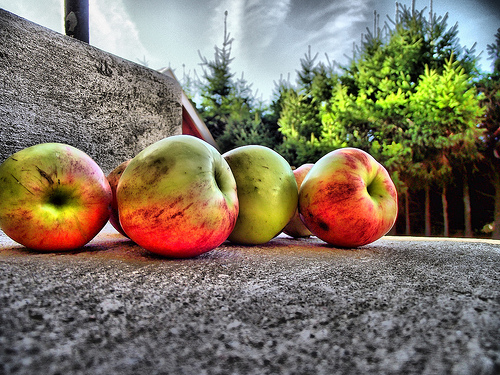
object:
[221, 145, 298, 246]
apple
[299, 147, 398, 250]
apple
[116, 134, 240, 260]
apple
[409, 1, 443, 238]
trees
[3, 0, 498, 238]
background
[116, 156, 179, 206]
marks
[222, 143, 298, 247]
skin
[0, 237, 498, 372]
ground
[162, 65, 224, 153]
roof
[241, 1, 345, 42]
clouds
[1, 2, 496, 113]
sky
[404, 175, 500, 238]
trunks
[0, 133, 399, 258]
apples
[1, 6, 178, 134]
wall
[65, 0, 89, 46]
pipe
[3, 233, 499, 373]
stone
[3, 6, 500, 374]
bench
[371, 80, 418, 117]
leaves